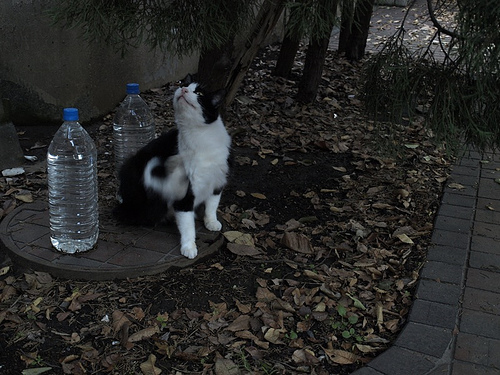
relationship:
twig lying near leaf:
[238, 246, 334, 271] [280, 228, 315, 255]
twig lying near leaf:
[238, 246, 334, 271] [223, 239, 263, 258]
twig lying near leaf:
[290, 301, 305, 321] [343, 290, 367, 310]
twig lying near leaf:
[290, 301, 305, 321] [122, 325, 161, 344]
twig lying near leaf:
[172, 320, 202, 345] [136, 348, 165, 373]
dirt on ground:
[228, 138, 376, 223] [229, 97, 417, 312]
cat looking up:
[135, 75, 227, 251] [137, 99, 164, 122]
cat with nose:
[135, 75, 227, 251] [170, 99, 194, 102]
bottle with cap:
[37, 76, 149, 245] [60, 109, 81, 133]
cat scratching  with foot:
[135, 75, 227, 251] [172, 225, 209, 263]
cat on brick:
[135, 75, 227, 251] [28, 69, 286, 279]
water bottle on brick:
[46, 110, 98, 254] [28, 69, 286, 279]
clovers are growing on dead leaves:
[334, 285, 378, 355] [311, 266, 401, 374]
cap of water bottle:
[49, 105, 83, 128] [42, 103, 104, 282]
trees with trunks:
[188, 54, 498, 112] [335, 100, 358, 123]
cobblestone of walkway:
[422, 129, 495, 371] [217, 245, 497, 375]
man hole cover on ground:
[14, 185, 254, 274] [25, 261, 253, 311]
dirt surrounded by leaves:
[228, 138, 376, 223] [292, 214, 374, 282]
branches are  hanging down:
[344, 50, 464, 123] [370, 101, 427, 129]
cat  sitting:
[135, 75, 227, 251] [141, 181, 249, 264]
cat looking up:
[135, 75, 227, 251] [166, 102, 212, 111]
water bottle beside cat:
[46, 110, 98, 254] [155, 109, 240, 272]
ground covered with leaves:
[237, 89, 424, 375] [332, 208, 399, 320]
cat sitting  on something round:
[135, 75, 227, 251] [112, 163, 259, 316]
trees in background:
[188, 54, 498, 112] [232, 103, 464, 216]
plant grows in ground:
[324, 295, 360, 345] [24, 52, 436, 361]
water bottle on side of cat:
[46, 110, 98, 254] [112, 69, 241, 258]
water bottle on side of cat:
[111, 80, 153, 160] [112, 69, 241, 258]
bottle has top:
[37, 76, 149, 245] [58, 103, 74, 123]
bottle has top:
[107, 78, 158, 162] [127, 81, 140, 99]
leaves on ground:
[44, 79, 404, 355] [24, 48, 474, 355]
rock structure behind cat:
[21, 7, 205, 126] [109, 65, 227, 267]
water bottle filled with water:
[46, 110, 98, 254] [46, 126, 96, 255]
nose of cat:
[177, 88, 187, 90] [135, 75, 227, 251]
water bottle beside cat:
[46, 110, 98, 254] [111, 73, 248, 248]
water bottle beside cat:
[111, 80, 153, 160] [111, 73, 248, 248]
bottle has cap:
[37, 76, 149, 245] [62, 105, 77, 124]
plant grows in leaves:
[324, 295, 360, 345] [86, 91, 406, 370]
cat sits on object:
[135, 75, 227, 251] [18, 189, 223, 274]